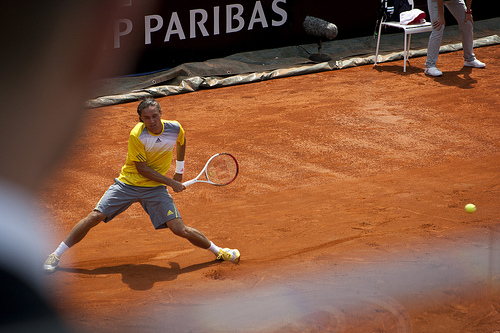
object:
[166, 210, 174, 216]
logo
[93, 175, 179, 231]
shorts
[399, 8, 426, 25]
towel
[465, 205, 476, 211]
ball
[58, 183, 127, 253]
leg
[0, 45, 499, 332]
floor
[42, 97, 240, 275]
man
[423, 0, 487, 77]
official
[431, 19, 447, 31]
hand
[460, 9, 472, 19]
hand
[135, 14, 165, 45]
letter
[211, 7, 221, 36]
letter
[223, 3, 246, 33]
letter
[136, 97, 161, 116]
hair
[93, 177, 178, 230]
gray pants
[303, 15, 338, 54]
microphone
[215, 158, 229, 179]
w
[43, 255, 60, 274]
sneakers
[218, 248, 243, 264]
sneakers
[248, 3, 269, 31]
letter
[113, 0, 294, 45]
paribas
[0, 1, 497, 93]
wall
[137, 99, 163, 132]
head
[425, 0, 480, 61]
pants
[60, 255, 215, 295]
shadow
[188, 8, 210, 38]
letter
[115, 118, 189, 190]
shirt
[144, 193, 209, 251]
leg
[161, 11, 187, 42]
letter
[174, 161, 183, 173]
sweatband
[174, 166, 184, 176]
wrist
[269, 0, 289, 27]
letter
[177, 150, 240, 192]
racket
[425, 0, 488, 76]
man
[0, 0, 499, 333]
court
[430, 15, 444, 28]
knees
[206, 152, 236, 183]
webbing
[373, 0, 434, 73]
bench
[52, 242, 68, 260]
socks